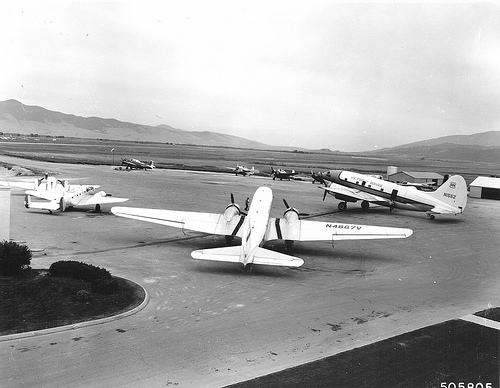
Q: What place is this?
A: It is an airport.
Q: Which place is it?
A: It is an airport.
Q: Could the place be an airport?
A: Yes, it is an airport.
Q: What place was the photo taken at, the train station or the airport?
A: It was taken at the airport.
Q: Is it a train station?
A: No, it is an airport.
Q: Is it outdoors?
A: Yes, it is outdoors.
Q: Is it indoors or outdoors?
A: It is outdoors.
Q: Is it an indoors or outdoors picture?
A: It is outdoors.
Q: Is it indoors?
A: No, it is outdoors.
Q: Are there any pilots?
A: No, there are no pilots.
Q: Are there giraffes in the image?
A: No, there are no giraffes.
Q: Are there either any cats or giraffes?
A: No, there are no giraffes or cats.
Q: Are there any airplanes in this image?
A: Yes, there is an airplane.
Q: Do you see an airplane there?
A: Yes, there is an airplane.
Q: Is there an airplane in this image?
A: Yes, there is an airplane.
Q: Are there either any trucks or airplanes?
A: Yes, there is an airplane.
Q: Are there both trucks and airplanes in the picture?
A: No, there is an airplane but no trucks.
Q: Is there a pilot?
A: No, there are no pilots.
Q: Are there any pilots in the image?
A: No, there are no pilots.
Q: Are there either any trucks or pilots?
A: No, there are no pilots or trucks.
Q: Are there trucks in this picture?
A: No, there are no trucks.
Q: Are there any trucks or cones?
A: No, there are no trucks or cones.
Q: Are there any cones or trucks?
A: No, there are no trucks or cones.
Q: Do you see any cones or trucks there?
A: No, there are no trucks or cones.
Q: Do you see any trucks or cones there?
A: No, there are no trucks or cones.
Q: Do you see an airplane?
A: Yes, there is an airplane.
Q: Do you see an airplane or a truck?
A: Yes, there is an airplane.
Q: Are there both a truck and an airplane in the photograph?
A: No, there is an airplane but no trucks.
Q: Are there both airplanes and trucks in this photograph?
A: No, there is an airplane but no trucks.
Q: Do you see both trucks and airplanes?
A: No, there is an airplane but no trucks.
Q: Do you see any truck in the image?
A: No, there are no trucks.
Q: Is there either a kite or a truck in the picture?
A: No, there are no trucks or kites.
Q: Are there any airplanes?
A: Yes, there is an airplane.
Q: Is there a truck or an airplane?
A: Yes, there is an airplane.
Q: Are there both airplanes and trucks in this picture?
A: No, there is an airplane but no trucks.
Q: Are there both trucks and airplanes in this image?
A: No, there is an airplane but no trucks.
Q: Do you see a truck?
A: No, there are no trucks.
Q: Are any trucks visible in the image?
A: No, there are no trucks.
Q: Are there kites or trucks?
A: No, there are no trucks or kites.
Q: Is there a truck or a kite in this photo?
A: No, there are no trucks or kites.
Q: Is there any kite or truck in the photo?
A: No, there are no trucks or kites.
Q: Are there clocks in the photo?
A: No, there are no clocks.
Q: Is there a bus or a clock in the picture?
A: No, there are no clocks or buses.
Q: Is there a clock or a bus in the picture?
A: No, there are no clocks or buses.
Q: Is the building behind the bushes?
A: Yes, the building is behind the bushes.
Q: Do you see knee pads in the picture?
A: No, there are no knee pads.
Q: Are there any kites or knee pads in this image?
A: No, there are no knee pads or kites.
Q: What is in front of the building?
A: The bushes are in front of the building.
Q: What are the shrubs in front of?
A: The shrubs are in front of the building.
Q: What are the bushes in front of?
A: The shrubs are in front of the building.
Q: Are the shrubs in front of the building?
A: Yes, the shrubs are in front of the building.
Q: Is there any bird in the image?
A: No, there are no birds.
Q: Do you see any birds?
A: No, there are no birds.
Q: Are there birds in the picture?
A: No, there are no birds.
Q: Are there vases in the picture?
A: No, there are no vases.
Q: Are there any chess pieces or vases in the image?
A: No, there are no vases or chess pieces.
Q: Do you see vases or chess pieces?
A: No, there are no vases or chess pieces.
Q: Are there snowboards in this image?
A: No, there are no snowboards.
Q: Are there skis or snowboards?
A: No, there are no snowboards or skis.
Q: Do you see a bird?
A: No, there are no birds.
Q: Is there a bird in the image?
A: No, there are no birds.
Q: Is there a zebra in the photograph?
A: No, there are no zebras.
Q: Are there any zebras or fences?
A: No, there are no zebras or fences.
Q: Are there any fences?
A: No, there are no fences.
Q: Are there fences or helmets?
A: No, there are no fences or helmets.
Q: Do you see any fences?
A: No, there are no fences.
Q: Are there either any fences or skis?
A: No, there are no fences or skis.